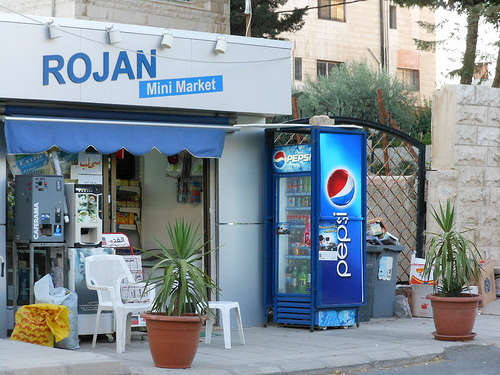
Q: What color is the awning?
A: Blue.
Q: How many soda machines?
A: One.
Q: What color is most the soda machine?
A: Blue.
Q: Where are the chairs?
A: On sidewalk.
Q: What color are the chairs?
A: White.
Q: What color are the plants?
A: Green.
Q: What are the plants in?
A: Pots.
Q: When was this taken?
A: During daylight.